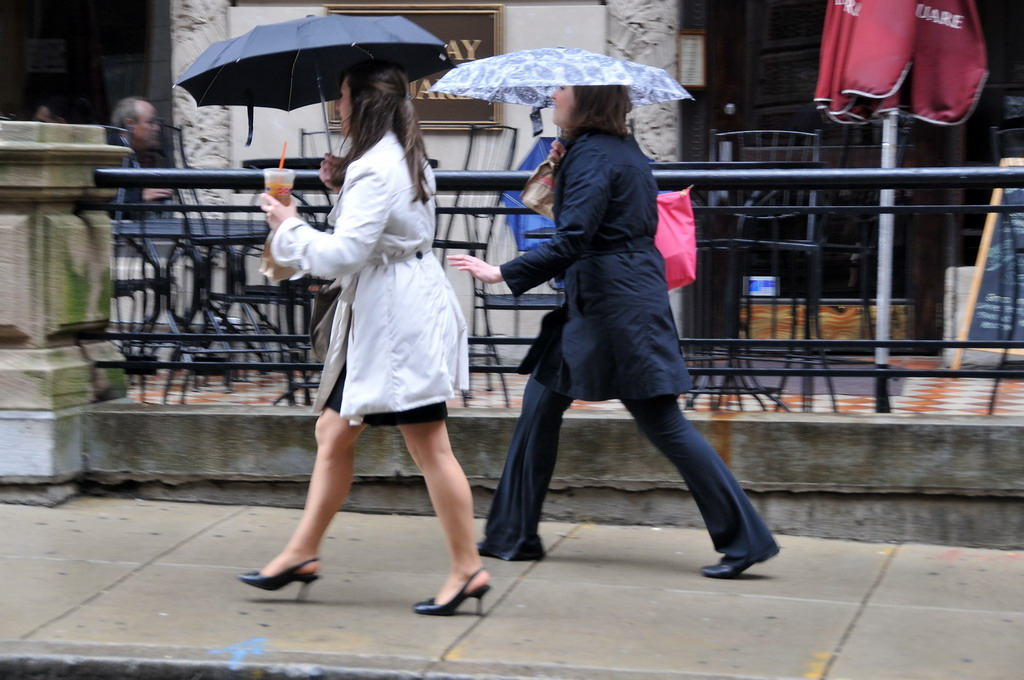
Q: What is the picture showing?
A: It is showing a sidewalk.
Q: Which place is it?
A: It is a sidewalk.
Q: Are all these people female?
A: No, they are both male and female.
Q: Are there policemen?
A: No, there are no policemen.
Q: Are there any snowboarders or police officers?
A: No, there are no police officers or snowboarders.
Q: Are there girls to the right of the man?
A: Yes, there is a girl to the right of the man.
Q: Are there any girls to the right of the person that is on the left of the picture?
A: Yes, there is a girl to the right of the man.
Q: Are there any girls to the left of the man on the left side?
A: No, the girl is to the right of the man.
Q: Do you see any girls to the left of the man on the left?
A: No, the girl is to the right of the man.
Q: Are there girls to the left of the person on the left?
A: No, the girl is to the right of the man.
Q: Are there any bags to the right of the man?
A: No, there is a girl to the right of the man.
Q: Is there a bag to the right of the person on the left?
A: No, there is a girl to the right of the man.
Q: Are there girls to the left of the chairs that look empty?
A: Yes, there is a girl to the left of the chairs.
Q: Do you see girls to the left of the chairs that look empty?
A: Yes, there is a girl to the left of the chairs.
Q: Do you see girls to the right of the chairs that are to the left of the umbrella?
A: No, the girl is to the left of the chairs.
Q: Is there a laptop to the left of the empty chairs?
A: No, there is a girl to the left of the chairs.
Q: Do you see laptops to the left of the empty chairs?
A: No, there is a girl to the left of the chairs.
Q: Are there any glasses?
A: No, there are no glasses.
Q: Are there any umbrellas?
A: Yes, there is an umbrella.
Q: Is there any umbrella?
A: Yes, there is an umbrella.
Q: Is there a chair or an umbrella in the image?
A: Yes, there is an umbrella.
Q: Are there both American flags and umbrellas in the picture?
A: No, there is an umbrella but no American flags.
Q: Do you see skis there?
A: No, there are no skis.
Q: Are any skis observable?
A: No, there are no skis.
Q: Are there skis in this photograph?
A: No, there are no skis.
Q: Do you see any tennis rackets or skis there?
A: No, there are no skis or tennis rackets.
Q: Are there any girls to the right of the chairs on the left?
A: Yes, there is a girl to the right of the chairs.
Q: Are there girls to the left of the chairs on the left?
A: No, the girl is to the right of the chairs.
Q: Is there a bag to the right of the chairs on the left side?
A: No, there is a girl to the right of the chairs.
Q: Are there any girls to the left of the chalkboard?
A: Yes, there is a girl to the left of the chalkboard.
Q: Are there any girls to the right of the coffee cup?
A: Yes, there is a girl to the right of the coffee cup.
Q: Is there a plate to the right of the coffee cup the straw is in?
A: No, there is a girl to the right of the coffee cup.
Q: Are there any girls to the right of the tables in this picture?
A: Yes, there is a girl to the right of the tables.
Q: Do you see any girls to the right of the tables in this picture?
A: Yes, there is a girl to the right of the tables.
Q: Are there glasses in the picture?
A: No, there are no glasses.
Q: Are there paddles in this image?
A: No, there are no paddles.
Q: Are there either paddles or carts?
A: No, there are no paddles or carts.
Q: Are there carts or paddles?
A: No, there are no paddles or carts.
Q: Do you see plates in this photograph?
A: No, there are no plates.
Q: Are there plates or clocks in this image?
A: No, there are no plates or clocks.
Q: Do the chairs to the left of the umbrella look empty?
A: Yes, the chairs are empty.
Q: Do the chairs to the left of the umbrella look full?
A: No, the chairs are empty.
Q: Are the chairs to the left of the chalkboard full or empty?
A: The chairs are empty.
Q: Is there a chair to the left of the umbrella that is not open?
A: Yes, there are chairs to the left of the umbrella.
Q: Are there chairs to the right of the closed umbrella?
A: No, the chairs are to the left of the umbrella.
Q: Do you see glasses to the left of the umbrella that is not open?
A: No, there are chairs to the left of the umbrella.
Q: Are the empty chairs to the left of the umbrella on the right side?
A: Yes, the chairs are to the left of the umbrella.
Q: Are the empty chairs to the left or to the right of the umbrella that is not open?
A: The chairs are to the left of the umbrella.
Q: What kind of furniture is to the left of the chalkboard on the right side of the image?
A: The pieces of furniture are chairs.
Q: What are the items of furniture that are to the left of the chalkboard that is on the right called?
A: The pieces of furniture are chairs.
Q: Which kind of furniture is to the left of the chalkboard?
A: The pieces of furniture are chairs.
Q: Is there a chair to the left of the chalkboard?
A: Yes, there are chairs to the left of the chalkboard.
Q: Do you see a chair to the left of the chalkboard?
A: Yes, there are chairs to the left of the chalkboard.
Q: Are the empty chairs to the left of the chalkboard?
A: Yes, the chairs are to the left of the chalkboard.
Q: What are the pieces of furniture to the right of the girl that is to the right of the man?
A: The pieces of furniture are chairs.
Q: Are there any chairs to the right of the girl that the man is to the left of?
A: Yes, there are chairs to the right of the girl.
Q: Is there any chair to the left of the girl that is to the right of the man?
A: No, the chairs are to the right of the girl.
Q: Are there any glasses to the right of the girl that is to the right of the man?
A: No, there are chairs to the right of the girl.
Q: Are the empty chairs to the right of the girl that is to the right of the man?
A: Yes, the chairs are to the right of the girl.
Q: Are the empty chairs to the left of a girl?
A: No, the chairs are to the right of a girl.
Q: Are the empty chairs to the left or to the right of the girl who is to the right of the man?
A: The chairs are to the right of the girl.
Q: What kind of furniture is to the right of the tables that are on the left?
A: The pieces of furniture are chairs.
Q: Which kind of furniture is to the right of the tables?
A: The pieces of furniture are chairs.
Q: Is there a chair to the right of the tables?
A: Yes, there are chairs to the right of the tables.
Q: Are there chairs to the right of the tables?
A: Yes, there are chairs to the right of the tables.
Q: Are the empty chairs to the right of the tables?
A: Yes, the chairs are to the right of the tables.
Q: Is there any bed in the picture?
A: No, there are no beds.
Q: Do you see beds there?
A: No, there are no beds.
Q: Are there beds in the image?
A: No, there are no beds.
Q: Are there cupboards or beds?
A: No, there are no beds or cupboards.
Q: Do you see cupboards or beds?
A: No, there are no beds or cupboards.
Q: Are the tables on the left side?
A: Yes, the tables are on the left of the image.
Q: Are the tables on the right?
A: No, the tables are on the left of the image.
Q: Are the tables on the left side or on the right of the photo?
A: The tables are on the left of the image.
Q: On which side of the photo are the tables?
A: The tables are on the left of the image.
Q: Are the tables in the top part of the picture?
A: Yes, the tables are in the top of the image.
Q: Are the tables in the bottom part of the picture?
A: No, the tables are in the top of the image.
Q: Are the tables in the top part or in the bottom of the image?
A: The tables are in the top of the image.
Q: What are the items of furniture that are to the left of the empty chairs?
A: The pieces of furniture are tables.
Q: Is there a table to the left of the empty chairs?
A: Yes, there are tables to the left of the chairs.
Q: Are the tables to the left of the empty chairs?
A: Yes, the tables are to the left of the chairs.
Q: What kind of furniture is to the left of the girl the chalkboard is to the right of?
A: The pieces of furniture are tables.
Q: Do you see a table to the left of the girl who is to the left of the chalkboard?
A: Yes, there are tables to the left of the girl.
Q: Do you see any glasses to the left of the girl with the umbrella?
A: No, there are tables to the left of the girl.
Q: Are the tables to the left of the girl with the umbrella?
A: Yes, the tables are to the left of the girl.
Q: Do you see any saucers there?
A: No, there are no saucers.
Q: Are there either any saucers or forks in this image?
A: No, there are no saucers or forks.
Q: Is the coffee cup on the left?
A: Yes, the coffee cup is on the left of the image.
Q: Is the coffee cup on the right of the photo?
A: No, the coffee cup is on the left of the image.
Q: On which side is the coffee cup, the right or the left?
A: The coffee cup is on the left of the image.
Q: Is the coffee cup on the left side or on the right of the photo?
A: The coffee cup is on the left of the image.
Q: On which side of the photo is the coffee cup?
A: The coffee cup is on the left of the image.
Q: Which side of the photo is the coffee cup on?
A: The coffee cup is on the left of the image.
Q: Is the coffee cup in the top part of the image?
A: Yes, the coffee cup is in the top of the image.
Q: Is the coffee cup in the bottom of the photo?
A: No, the coffee cup is in the top of the image.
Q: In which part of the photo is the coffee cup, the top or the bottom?
A: The coffee cup is in the top of the image.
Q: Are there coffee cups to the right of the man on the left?
A: Yes, there is a coffee cup to the right of the man.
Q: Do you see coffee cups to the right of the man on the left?
A: Yes, there is a coffee cup to the right of the man.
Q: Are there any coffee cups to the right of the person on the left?
A: Yes, there is a coffee cup to the right of the man.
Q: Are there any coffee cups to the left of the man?
A: No, the coffee cup is to the right of the man.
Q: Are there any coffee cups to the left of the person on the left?
A: No, the coffee cup is to the right of the man.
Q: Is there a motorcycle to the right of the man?
A: No, there is a coffee cup to the right of the man.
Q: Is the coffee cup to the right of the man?
A: Yes, the coffee cup is to the right of the man.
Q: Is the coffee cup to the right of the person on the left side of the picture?
A: Yes, the coffee cup is to the right of the man.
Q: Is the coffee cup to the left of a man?
A: No, the coffee cup is to the right of a man.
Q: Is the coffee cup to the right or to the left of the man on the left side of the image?
A: The coffee cup is to the right of the man.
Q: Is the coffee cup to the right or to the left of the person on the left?
A: The coffee cup is to the right of the man.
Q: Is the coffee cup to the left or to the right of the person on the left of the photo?
A: The coffee cup is to the right of the man.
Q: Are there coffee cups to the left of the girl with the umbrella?
A: Yes, there is a coffee cup to the left of the girl.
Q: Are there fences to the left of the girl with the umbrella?
A: No, there is a coffee cup to the left of the girl.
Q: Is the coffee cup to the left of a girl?
A: Yes, the coffee cup is to the left of a girl.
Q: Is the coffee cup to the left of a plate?
A: No, the coffee cup is to the left of a girl.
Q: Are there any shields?
A: No, there are no shields.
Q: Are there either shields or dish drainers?
A: No, there are no shields or dish drainers.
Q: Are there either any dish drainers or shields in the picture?
A: No, there are no shields or dish drainers.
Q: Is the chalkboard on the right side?
A: Yes, the chalkboard is on the right of the image.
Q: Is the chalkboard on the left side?
A: No, the chalkboard is on the right of the image.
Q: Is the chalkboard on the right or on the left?
A: The chalkboard is on the right of the image.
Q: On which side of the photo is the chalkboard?
A: The chalkboard is on the right of the image.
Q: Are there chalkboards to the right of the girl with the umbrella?
A: Yes, there is a chalkboard to the right of the girl.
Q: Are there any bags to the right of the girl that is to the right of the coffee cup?
A: No, there is a chalkboard to the right of the girl.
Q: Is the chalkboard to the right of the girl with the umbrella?
A: Yes, the chalkboard is to the right of the girl.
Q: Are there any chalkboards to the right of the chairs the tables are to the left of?
A: Yes, there is a chalkboard to the right of the chairs.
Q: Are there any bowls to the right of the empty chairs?
A: No, there is a chalkboard to the right of the chairs.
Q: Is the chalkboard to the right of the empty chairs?
A: Yes, the chalkboard is to the right of the chairs.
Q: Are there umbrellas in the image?
A: Yes, there is an umbrella.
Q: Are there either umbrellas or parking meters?
A: Yes, there is an umbrella.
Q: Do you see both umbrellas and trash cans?
A: No, there is an umbrella but no trash cans.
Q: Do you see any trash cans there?
A: No, there are no trash cans.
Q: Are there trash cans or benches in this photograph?
A: No, there are no trash cans or benches.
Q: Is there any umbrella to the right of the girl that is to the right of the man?
A: Yes, there is an umbrella to the right of the girl.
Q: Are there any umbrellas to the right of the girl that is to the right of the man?
A: Yes, there is an umbrella to the right of the girl.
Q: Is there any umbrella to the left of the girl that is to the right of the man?
A: No, the umbrella is to the right of the girl.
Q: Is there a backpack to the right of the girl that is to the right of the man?
A: No, there is an umbrella to the right of the girl.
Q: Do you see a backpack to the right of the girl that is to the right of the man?
A: No, there is an umbrella to the right of the girl.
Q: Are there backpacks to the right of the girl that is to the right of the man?
A: No, there is an umbrella to the right of the girl.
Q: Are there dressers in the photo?
A: No, there are no dressers.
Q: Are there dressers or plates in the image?
A: No, there are no dressers or plates.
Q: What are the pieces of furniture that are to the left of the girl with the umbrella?
A: The pieces of furniture are chairs.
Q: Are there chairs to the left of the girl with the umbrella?
A: Yes, there are chairs to the left of the girl.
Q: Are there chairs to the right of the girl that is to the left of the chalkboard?
A: No, the chairs are to the left of the girl.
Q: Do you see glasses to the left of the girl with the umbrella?
A: No, there are chairs to the left of the girl.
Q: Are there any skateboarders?
A: No, there are no skateboarders.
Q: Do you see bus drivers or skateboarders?
A: No, there are no skateboarders or bus drivers.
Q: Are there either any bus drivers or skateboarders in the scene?
A: No, there are no skateboarders or bus drivers.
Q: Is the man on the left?
A: Yes, the man is on the left of the image.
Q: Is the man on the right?
A: No, the man is on the left of the image.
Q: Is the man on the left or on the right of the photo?
A: The man is on the left of the image.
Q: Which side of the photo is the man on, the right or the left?
A: The man is on the left of the image.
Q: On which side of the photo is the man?
A: The man is on the left of the image.